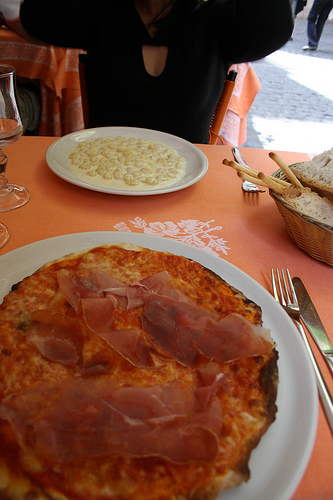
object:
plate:
[45, 125, 207, 197]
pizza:
[0, 238, 278, 500]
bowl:
[0, 231, 317, 499]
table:
[0, 136, 333, 500]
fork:
[269, 263, 333, 436]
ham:
[0, 376, 221, 470]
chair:
[78, 55, 235, 144]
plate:
[0, 232, 318, 500]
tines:
[269, 264, 297, 320]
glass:
[0, 62, 32, 210]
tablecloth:
[0, 135, 333, 500]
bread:
[268, 150, 303, 188]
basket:
[269, 143, 333, 264]